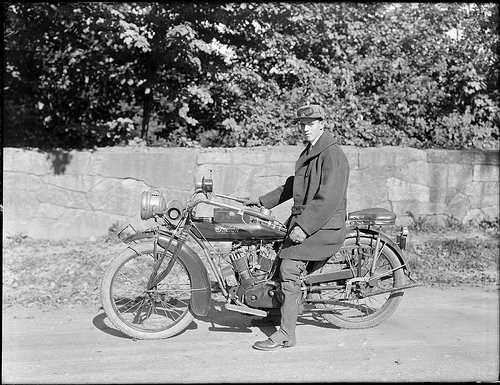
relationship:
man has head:
[234, 107, 356, 327] [292, 104, 326, 146]